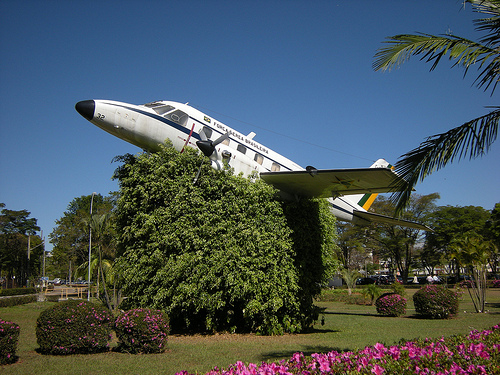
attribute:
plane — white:
[73, 97, 431, 234]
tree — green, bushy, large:
[116, 135, 340, 336]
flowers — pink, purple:
[0, 318, 22, 366]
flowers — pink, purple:
[35, 299, 112, 353]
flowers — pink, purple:
[113, 306, 171, 353]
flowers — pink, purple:
[375, 290, 406, 316]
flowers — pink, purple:
[412, 282, 459, 318]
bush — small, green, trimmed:
[0, 317, 19, 363]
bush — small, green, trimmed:
[37, 299, 113, 355]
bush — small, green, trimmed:
[114, 306, 170, 354]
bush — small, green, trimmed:
[376, 290, 405, 316]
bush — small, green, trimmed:
[413, 281, 463, 316]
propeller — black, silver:
[194, 126, 232, 189]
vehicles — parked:
[34, 275, 95, 288]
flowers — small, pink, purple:
[175, 323, 499, 374]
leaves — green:
[373, 3, 499, 236]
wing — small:
[256, 164, 418, 195]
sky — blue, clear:
[3, 3, 497, 257]